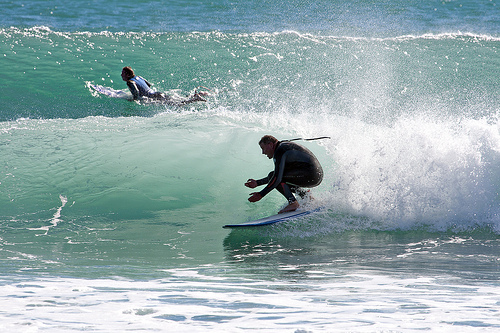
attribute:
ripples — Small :
[33, 145, 103, 196]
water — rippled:
[33, 151, 408, 316]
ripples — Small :
[121, 273, 399, 332]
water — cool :
[37, 236, 458, 311]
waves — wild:
[1, 1, 498, 331]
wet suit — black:
[237, 129, 344, 243]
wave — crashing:
[0, 103, 496, 224]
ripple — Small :
[100, 282, 155, 292]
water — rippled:
[340, 235, 445, 307]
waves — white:
[297, 93, 489, 276]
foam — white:
[1, 260, 498, 332]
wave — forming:
[2, 22, 499, 72]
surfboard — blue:
[216, 207, 320, 227]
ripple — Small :
[124, 302, 248, 326]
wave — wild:
[10, 27, 495, 264]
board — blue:
[221, 206, 323, 228]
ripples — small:
[0, 230, 499, 333]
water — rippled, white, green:
[0, 0, 499, 330]